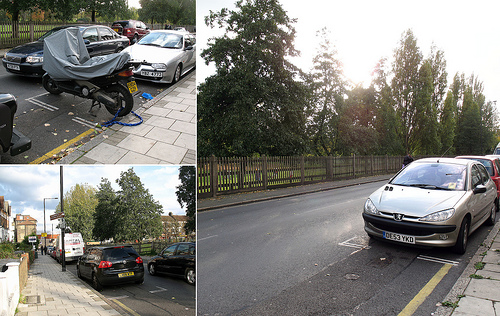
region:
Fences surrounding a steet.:
[217, 145, 375, 192]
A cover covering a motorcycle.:
[33, 22, 168, 124]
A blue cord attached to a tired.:
[106, 105, 153, 140]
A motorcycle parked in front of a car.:
[41, 28, 172, 123]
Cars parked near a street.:
[36, 223, 168, 312]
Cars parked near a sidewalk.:
[41, 229, 153, 314]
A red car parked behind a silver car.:
[454, 133, 499, 178]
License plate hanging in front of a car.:
[373, 217, 428, 267]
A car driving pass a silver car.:
[10, 13, 144, 82]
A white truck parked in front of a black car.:
[50, 233, 111, 273]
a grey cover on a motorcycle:
[37, 26, 128, 81]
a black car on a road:
[0, 18, 131, 79]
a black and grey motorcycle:
[38, 66, 143, 122]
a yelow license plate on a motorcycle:
[124, 74, 143, 94]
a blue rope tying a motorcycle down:
[97, 105, 145, 132]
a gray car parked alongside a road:
[355, 153, 494, 268]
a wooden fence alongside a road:
[195, 151, 405, 204]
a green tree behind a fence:
[200, 1, 309, 156]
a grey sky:
[197, 1, 498, 117]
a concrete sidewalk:
[61, 69, 194, 162]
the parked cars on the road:
[361, 142, 498, 252]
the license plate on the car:
[382, 230, 415, 245]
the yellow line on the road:
[392, 262, 454, 314]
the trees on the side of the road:
[195, 0, 498, 157]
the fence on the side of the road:
[198, 151, 465, 200]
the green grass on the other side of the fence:
[195, 162, 400, 197]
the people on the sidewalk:
[37, 245, 48, 253]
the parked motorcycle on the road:
[41, 25, 136, 117]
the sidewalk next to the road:
[15, 245, 121, 314]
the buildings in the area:
[0, 195, 201, 313]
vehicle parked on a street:
[356, 150, 498, 258]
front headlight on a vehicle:
[418, 202, 457, 225]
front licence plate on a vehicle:
[381, 227, 419, 248]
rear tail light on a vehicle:
[131, 254, 146, 265]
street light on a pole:
[39, 191, 60, 205]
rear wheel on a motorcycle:
[99, 80, 136, 119]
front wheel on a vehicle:
[146, 258, 159, 277]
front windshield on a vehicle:
[386, 157, 471, 194]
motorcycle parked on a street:
[36, 22, 141, 122]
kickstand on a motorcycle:
[87, 93, 104, 113]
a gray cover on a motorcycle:
[40, 25, 134, 83]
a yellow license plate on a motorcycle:
[124, 75, 139, 96]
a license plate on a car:
[115, 269, 140, 280]